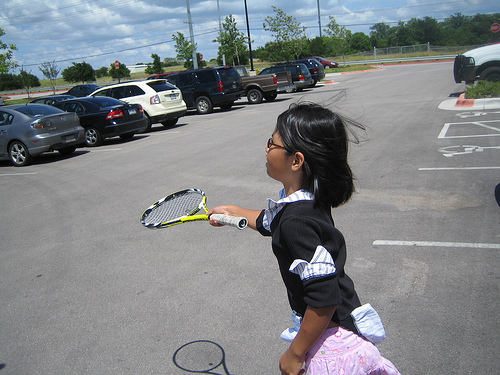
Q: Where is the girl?
A: On the street.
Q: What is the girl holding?
A: A racket.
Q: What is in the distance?
A: Trees.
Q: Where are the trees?
A: In the distance.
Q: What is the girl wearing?
A: Black and white shirt.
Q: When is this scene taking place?
A: Daytime.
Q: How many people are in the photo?
A: One.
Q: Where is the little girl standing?
A: Parking lot.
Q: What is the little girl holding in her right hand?
A: Tennis racket.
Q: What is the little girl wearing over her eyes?
A: Eyeglasses.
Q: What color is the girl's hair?
A: Black.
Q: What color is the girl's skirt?
A: Pink.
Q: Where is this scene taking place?
A: Running through the parking lotb.